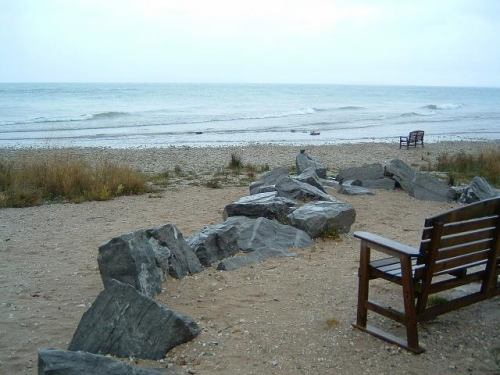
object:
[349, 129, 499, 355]
two benches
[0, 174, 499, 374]
foreground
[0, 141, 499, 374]
sand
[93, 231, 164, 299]
gray rock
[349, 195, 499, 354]
wooden bench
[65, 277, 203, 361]
rock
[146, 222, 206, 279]
rock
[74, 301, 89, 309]
white rocks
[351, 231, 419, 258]
arm rest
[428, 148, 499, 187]
grass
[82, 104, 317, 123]
waves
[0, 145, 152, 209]
grass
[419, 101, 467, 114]
waves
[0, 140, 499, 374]
bench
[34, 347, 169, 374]
rock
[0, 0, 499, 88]
sky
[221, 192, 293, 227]
rock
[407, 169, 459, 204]
rock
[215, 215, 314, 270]
rock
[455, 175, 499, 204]
rock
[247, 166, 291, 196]
rock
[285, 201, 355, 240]
rock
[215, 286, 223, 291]
tiny rock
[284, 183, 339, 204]
rock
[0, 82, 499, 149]
water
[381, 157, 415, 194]
rocks